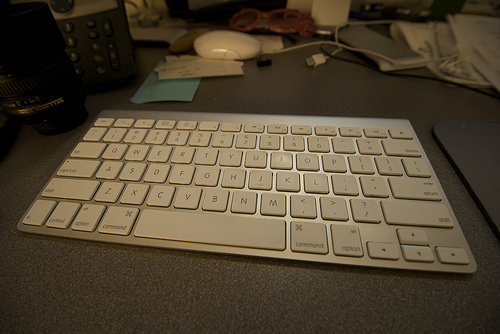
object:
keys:
[21, 198, 60, 228]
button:
[289, 219, 329, 255]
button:
[329, 222, 363, 258]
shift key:
[379, 199, 455, 230]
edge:
[18, 221, 478, 277]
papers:
[445, 12, 500, 96]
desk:
[0, 19, 500, 334]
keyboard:
[12, 108, 478, 276]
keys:
[330, 136, 357, 156]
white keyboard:
[133, 208, 287, 253]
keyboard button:
[229, 190, 257, 215]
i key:
[269, 151, 292, 170]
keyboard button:
[97, 205, 140, 237]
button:
[117, 160, 148, 182]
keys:
[395, 227, 430, 247]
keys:
[435, 246, 470, 265]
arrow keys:
[365, 240, 400, 261]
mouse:
[192, 29, 262, 61]